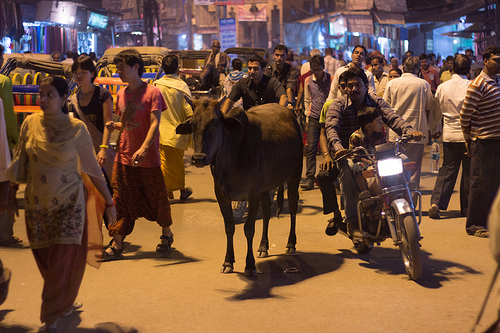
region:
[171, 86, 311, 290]
a black horned cow standing in the street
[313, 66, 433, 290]
two men on a motorcycle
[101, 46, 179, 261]
a young man walking in the street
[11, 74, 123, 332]
a woman walking in the street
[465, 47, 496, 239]
a man standing in the street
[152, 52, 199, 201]
a woman walking in the street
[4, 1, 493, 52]
buildings in the distance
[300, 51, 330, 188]
a man walking in the street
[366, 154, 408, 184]
a motorcycle headlight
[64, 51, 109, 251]
a young girl walking the street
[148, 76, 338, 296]
cow on a street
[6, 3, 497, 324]
busy street in india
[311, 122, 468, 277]
a small black motorcycle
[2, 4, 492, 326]
a busy urban street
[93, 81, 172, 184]
a bright red tee shirt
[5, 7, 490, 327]
a busy city square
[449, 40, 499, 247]
man in a striped shirt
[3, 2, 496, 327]
a busy indian market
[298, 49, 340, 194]
man in a purple shirt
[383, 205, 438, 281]
part of a wheel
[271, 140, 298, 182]
stomach of a cow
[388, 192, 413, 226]
part of a guard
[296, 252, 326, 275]
part of a shade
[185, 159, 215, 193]
mouth of a cow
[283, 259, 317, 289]
edge of a cow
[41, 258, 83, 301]
part of a cloth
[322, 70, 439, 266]
two men riding a moped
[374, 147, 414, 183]
the white light of a moped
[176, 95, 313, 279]
a cow standing in the street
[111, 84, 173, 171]
young man wearing a red T-shirt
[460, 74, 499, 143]
man wearing an orange and white striped shirt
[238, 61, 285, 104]
man wearing a black shirt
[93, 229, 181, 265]
young man wearing black sandals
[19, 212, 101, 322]
woman wearing a long red skirt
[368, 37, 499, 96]
bustling crowd in the street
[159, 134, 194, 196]
woman with a long yellow skirt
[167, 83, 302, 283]
cow on street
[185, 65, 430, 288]
people on a motorcycle beside a cow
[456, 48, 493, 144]
man wearing a striped shirt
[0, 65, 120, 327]
woman wearing a brown traditional Indian outfit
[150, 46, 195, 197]
woman wearing a yellow outfit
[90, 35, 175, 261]
young man wearing sandals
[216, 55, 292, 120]
man wearing a black polo shirt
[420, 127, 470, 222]
man wearing black pants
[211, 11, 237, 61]
sign in the distance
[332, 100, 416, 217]
child on front of motorbike